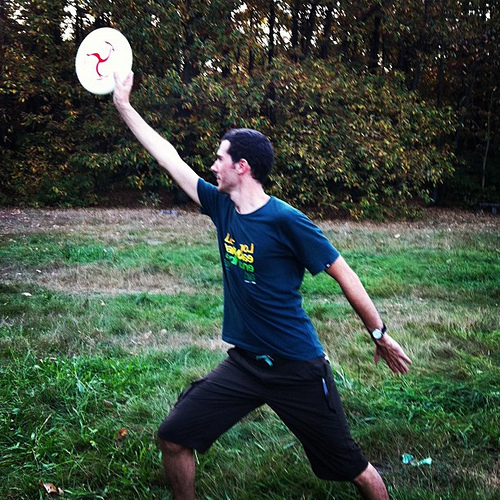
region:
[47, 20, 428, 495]
a man who has just caught a frisbee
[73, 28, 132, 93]
a red and white Frisbee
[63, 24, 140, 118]
a hand holding a frisbee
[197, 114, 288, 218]
the head of a man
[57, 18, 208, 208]
the arm of a man holding a frisbee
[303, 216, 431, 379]
the arm of a man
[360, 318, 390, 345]
a watch on the wrist of a man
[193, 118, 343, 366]
a man who is wearing a blue t-shirt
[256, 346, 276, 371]
the drawstring for a pair of shorts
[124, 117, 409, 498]
this is a man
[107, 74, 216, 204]
the hand is lifted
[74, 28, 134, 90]
this is a frisbee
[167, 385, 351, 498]
these are the legs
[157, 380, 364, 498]
the legs are apart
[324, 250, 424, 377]
this is the hand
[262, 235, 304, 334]
this is a t shirt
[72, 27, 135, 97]
the frisbee is white in color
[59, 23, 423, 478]
man holding the frisbee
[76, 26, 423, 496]
man on the grass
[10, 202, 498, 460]
the grass is untrimmed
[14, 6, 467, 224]
trees behind the man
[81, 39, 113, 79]
the logo on the frisbee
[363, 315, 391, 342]
the watch on the wrist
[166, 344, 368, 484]
man wearing shorts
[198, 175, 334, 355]
man wearing t shirt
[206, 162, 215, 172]
nose of the man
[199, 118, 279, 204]
head of the man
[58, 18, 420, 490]
man with frisbee in hand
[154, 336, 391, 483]
shorts on a man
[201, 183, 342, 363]
shirt on the man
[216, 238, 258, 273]
image on the shirt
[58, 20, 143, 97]
frisbee in man's hand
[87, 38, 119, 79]
image on the frisbee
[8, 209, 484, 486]
ground man stands on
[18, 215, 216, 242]
ground with brown grass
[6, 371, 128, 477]
ground with green grass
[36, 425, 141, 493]
leaves on the ground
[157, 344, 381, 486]
Man wearing shorts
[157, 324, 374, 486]
Man is wearing shorts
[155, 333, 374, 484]
Man wearing black shorts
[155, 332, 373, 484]
Man is wearing black shorts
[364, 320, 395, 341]
Man wearing a watch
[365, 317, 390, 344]
Man is wearing a watch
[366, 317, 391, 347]
Man wearing a wrist watch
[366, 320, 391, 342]
Man is wearing a wrist watch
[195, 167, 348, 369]
Man wearing a shirt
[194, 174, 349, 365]
Man is wearing a shirt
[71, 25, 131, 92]
A white Frisbee with a red emblem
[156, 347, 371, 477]
A pair of dark shorts with blue drawstring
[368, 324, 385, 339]
A black strapped watch with white face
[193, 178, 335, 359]
A blue short sleeve shirt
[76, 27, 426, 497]
A man throwing a white Frisbee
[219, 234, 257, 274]
yellow and green writing on a tee shirt